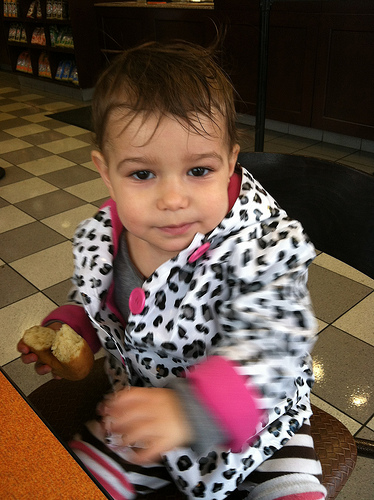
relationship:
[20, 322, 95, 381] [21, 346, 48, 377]
bagel in hand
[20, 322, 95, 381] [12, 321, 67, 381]
bagel in hand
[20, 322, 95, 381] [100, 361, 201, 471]
bagel in hand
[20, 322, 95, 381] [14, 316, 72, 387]
bagel in hand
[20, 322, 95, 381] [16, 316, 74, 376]
bagel in hand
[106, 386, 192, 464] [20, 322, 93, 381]
hand holding bagel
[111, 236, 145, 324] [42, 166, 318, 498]
shirt under jacket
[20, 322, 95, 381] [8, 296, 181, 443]
bagel in hand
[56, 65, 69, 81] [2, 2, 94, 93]
chips on display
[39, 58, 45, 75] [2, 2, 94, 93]
snack on display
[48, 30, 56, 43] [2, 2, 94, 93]
snack on display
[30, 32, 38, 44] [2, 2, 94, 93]
snack on display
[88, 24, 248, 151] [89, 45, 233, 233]
brown hair on head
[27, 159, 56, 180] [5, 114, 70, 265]
tile on ground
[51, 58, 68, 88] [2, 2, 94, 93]
chips on display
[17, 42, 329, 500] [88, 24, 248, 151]
baby with brown hair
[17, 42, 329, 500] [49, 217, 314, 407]
baby wearing an jacket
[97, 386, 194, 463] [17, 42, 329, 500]
hand of baby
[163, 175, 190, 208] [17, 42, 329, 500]
nose of baby